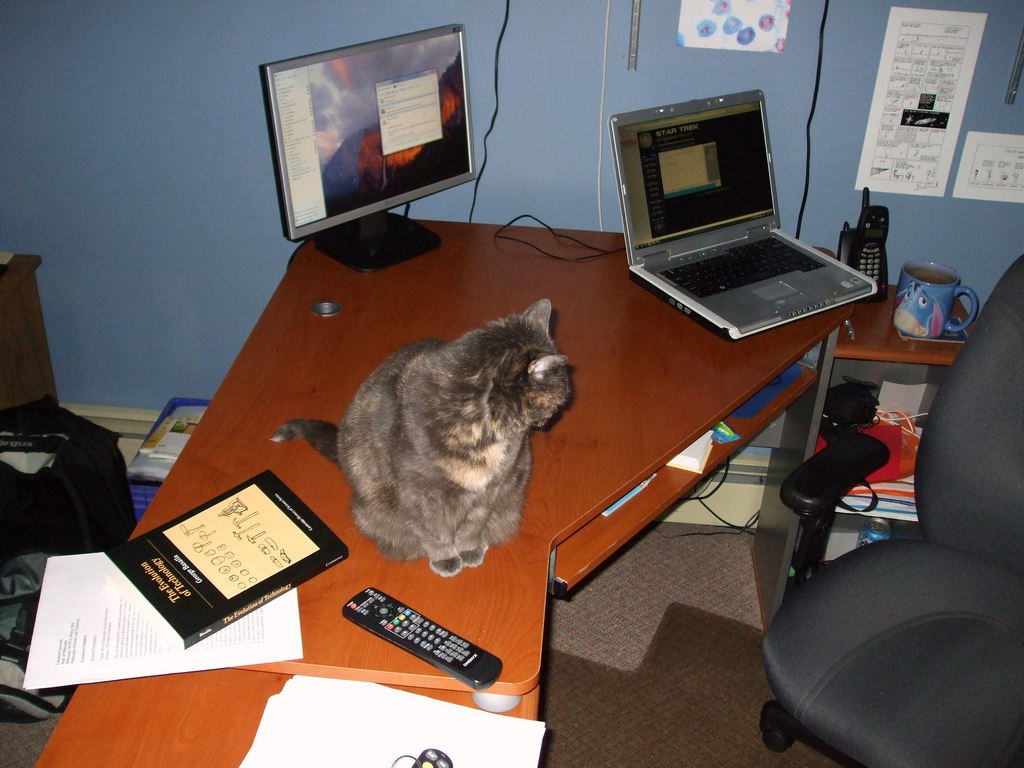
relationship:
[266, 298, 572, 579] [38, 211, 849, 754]
cat on table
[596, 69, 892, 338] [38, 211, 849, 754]
laptop on table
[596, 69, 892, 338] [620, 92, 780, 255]
laptop has screen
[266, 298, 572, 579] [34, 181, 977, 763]
cat on desk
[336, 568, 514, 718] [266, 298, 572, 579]
control next to cat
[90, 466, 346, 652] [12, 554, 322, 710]
book on top of papers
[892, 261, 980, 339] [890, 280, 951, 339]
mug with eeyore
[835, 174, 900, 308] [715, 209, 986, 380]
phone on shelf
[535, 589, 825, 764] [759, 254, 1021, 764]
mat under chair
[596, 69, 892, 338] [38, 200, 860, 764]
laptop on desk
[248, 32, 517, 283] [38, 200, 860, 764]
desktop on desk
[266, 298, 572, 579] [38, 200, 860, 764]
cat sitting on desk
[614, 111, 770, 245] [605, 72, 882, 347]
screen attached to laptop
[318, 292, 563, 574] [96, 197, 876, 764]
cat sitting on top of table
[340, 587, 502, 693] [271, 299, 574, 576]
control next to cat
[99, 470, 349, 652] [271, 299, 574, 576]
book by cat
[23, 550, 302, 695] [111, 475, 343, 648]
paper underneath textbook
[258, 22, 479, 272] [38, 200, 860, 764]
desktop on desk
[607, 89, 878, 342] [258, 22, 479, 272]
laptop in front of desktop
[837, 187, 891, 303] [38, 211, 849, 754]
phone on table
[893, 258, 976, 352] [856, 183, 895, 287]
mug next to phone